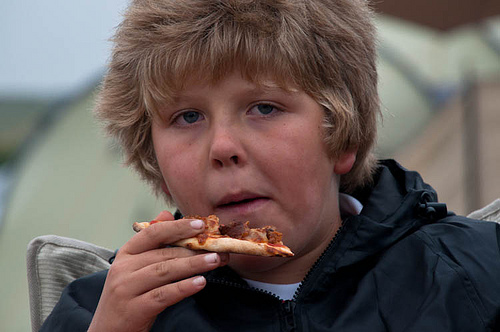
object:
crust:
[132, 215, 299, 258]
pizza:
[129, 212, 298, 260]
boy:
[34, 1, 498, 330]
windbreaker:
[38, 158, 500, 329]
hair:
[87, 2, 388, 206]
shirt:
[239, 279, 304, 302]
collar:
[337, 189, 363, 218]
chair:
[23, 195, 496, 327]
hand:
[81, 216, 231, 330]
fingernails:
[204, 251, 220, 265]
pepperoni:
[146, 217, 159, 226]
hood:
[172, 158, 449, 225]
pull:
[280, 297, 299, 330]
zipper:
[192, 211, 370, 330]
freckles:
[210, 131, 237, 144]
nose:
[205, 113, 250, 169]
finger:
[122, 217, 207, 253]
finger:
[127, 246, 231, 268]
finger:
[130, 275, 207, 308]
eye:
[163, 105, 205, 129]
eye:
[245, 99, 289, 120]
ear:
[333, 98, 361, 175]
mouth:
[212, 189, 275, 219]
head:
[87, 0, 386, 276]